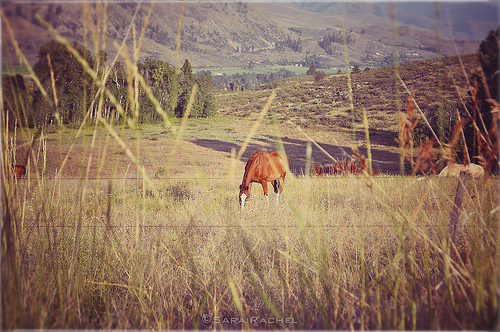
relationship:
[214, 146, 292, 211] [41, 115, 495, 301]
horse in field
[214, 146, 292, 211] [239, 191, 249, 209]
horse has stripe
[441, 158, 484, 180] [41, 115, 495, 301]
rock in field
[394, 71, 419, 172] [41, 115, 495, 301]
tree in field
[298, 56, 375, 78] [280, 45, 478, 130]
trees on hill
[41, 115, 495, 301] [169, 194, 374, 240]
field has grass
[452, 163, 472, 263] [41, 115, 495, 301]
post in field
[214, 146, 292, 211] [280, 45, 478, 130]
horse near hill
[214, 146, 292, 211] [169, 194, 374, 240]
horse eating grass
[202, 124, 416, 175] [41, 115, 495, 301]
shadows on field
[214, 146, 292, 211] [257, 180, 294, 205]
horse has legs